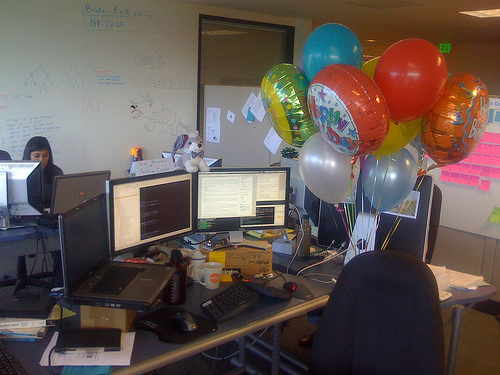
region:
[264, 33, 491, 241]
multiple colorful balloons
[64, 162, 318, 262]
two computer TV monitors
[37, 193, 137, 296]
a laptop with no power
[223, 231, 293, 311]
birthday card with signatures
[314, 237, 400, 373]
black office desk chair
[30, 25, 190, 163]
large white board behind people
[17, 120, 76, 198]
a girl with brown hair looking down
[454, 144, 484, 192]
multiple pink sticky notes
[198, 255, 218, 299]
an orange and white mug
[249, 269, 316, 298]
a black keyboard attatched to monitors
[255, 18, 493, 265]
The bouquet of birthday balloons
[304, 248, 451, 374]
An office chair is gray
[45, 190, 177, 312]
The laptop is black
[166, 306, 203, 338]
The mouse is on the desk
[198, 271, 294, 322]
The keyboard is on the desk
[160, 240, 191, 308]
The water bottle on the desk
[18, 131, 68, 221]
A woman sitting at her desk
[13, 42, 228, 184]
A whiteboard in the office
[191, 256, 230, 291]
A white coffee club on the desk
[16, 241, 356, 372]
The desk is gray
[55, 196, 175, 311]
A black laptop computer.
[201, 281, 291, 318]
a black keyboard.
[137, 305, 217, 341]
A black mousepad.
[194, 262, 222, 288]
A beige and orange mug.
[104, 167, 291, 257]
Two flatscreen black framed computer monitors.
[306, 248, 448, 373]
The black back of a chair.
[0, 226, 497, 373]
A grey computer desk.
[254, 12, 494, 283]
A lot of balloons.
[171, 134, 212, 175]
A small stuffed animal.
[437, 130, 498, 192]
Bright pink post it notes.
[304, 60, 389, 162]
red mylar balloon with message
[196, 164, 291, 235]
wide screen computer monitor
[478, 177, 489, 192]
used post-it note stuck to wall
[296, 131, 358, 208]
inflated white rubber balloon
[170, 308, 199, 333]
silver cordless computer mouse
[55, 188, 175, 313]
laptop in open position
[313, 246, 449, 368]
rear of black office chair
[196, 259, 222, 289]
white coffee mug with orange logo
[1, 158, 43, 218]
rear of wide screen computer monitor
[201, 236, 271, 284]
small closed cardboard box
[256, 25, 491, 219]
Bunch of helium balloons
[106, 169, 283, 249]
Two computer monitors side by side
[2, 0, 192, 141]
Dry erase board with writing on it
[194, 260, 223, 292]
White coffee cup with orange logo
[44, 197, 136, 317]
Black laptop not turned on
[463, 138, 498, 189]
Pink sticky notes on white board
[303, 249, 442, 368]
Black office chair back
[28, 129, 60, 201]
Young woman working in office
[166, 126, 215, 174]
Stuffed dog with winter hat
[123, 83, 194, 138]
Drawing of triceratops